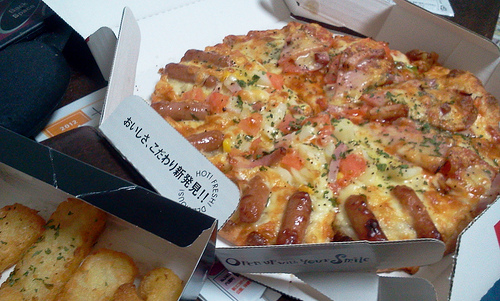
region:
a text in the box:
[93, 95, 245, 215]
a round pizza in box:
[155, 41, 497, 242]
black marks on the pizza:
[231, 79, 285, 139]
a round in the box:
[173, 163, 236, 217]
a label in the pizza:
[111, 113, 293, 239]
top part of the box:
[81, 175, 223, 255]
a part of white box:
[437, 205, 496, 297]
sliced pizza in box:
[104, 1, 497, 298]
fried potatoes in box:
[0, 123, 222, 297]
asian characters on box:
[122, 116, 209, 199]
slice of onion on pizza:
[231, 144, 288, 170]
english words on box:
[224, 253, 376, 269]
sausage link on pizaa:
[281, 191, 310, 247]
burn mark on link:
[367, 216, 385, 239]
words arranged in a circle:
[176, 169, 219, 213]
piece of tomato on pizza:
[341, 154, 364, 183]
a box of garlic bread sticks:
[0, 198, 97, 297]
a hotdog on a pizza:
[276, 186, 311, 247]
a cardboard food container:
[37, 7, 238, 227]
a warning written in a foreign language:
[121, 115, 206, 205]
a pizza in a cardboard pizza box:
[151, 21, 498, 244]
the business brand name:
[223, 251, 372, 272]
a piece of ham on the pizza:
[324, 140, 349, 185]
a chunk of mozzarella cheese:
[310, 183, 335, 243]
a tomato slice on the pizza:
[208, 91, 228, 114]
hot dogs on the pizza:
[144, 17, 497, 242]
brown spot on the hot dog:
[365, 219, 382, 235]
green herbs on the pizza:
[155, 34, 495, 236]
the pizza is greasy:
[148, 32, 498, 243]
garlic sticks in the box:
[2, 164, 202, 299]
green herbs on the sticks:
[1, 191, 121, 296]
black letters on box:
[213, 225, 378, 288]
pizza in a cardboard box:
[41, 2, 498, 276]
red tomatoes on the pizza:
[266, 145, 372, 192]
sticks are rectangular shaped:
[0, 177, 187, 299]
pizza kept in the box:
[137, 20, 492, 295]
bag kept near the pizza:
[1, 8, 86, 128]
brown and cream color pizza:
[151, 33, 485, 251]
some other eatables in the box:
[3, 198, 149, 299]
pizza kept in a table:
[105, 19, 499, 273]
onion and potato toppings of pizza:
[232, 53, 383, 194]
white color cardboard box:
[102, 16, 167, 211]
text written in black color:
[124, 116, 211, 196]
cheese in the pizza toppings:
[253, 57, 372, 197]